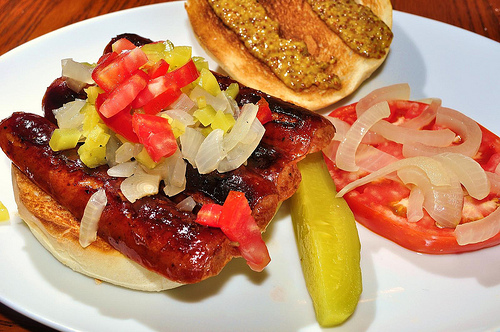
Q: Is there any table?
A: Yes, there is a table.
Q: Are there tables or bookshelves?
A: Yes, there is a table.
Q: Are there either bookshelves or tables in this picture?
A: Yes, there is a table.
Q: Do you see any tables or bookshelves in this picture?
A: Yes, there is a table.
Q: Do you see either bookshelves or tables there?
A: Yes, there is a table.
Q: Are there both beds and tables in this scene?
A: No, there is a table but no beds.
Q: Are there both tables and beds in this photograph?
A: No, there is a table but no beds.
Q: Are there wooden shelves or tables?
A: Yes, there is a wood table.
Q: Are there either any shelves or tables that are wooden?
A: Yes, the table is wooden.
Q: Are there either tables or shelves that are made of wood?
A: Yes, the table is made of wood.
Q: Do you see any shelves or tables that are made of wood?
A: Yes, the table is made of wood.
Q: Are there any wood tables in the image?
A: Yes, there is a wood table.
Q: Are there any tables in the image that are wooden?
A: Yes, there is a table that is wooden.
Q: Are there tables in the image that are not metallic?
A: Yes, there is a wooden table.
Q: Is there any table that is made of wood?
A: Yes, there is a table that is made of wood.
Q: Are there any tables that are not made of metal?
A: Yes, there is a table that is made of wood.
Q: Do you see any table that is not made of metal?
A: Yes, there is a table that is made of wood.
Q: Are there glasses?
A: No, there are no glasses.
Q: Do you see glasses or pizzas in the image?
A: No, there are no glasses or pizzas.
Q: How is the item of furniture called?
A: The piece of furniture is a table.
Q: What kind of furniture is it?
A: The piece of furniture is a table.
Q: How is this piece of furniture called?
A: This is a table.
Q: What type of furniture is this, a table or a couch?
A: This is a table.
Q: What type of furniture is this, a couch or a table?
A: This is a table.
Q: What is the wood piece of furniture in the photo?
A: The piece of furniture is a table.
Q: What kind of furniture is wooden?
A: The furniture is a table.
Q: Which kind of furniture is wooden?
A: The furniture is a table.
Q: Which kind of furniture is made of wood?
A: The furniture is a table.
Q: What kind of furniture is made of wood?
A: The furniture is a table.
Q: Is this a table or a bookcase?
A: This is a table.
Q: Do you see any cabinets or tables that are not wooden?
A: No, there is a table but it is wooden.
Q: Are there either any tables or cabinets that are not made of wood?
A: No, there is a table but it is made of wood.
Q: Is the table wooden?
A: Yes, the table is wooden.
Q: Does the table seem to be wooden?
A: Yes, the table is wooden.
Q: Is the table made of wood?
A: Yes, the table is made of wood.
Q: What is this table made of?
A: The table is made of wood.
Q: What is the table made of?
A: The table is made of wood.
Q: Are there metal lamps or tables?
A: No, there is a table but it is wooden.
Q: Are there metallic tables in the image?
A: No, there is a table but it is wooden.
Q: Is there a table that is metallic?
A: No, there is a table but it is wooden.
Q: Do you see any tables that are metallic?
A: No, there is a table but it is wooden.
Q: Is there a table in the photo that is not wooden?
A: No, there is a table but it is wooden.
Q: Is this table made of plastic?
A: No, the table is made of wood.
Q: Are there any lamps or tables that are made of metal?
A: No, there is a table but it is made of wood.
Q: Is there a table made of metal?
A: No, there is a table but it is made of wood.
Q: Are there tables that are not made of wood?
A: No, there is a table but it is made of wood.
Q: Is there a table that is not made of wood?
A: No, there is a table but it is made of wood.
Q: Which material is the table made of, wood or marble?
A: The table is made of wood.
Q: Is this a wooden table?
A: Yes, this is a wooden table.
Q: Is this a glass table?
A: No, this is a wooden table.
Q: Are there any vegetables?
A: Yes, there are vegetables.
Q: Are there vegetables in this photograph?
A: Yes, there are vegetables.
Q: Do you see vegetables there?
A: Yes, there are vegetables.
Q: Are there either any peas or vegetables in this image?
A: Yes, there are vegetables.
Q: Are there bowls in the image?
A: No, there are no bowls.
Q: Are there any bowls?
A: No, there are no bowls.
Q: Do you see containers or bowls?
A: No, there are no bowls or containers.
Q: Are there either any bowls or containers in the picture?
A: No, there are no bowls or containers.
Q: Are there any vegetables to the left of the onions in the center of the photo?
A: Yes, there are vegetables to the left of the onions.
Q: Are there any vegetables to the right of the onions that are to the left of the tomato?
A: No, the vegetables are to the left of the onions.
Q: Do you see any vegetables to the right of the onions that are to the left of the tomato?
A: No, the vegetables are to the left of the onions.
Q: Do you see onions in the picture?
A: Yes, there are onions.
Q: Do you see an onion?
A: Yes, there are onions.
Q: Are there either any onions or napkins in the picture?
A: Yes, there are onions.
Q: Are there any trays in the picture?
A: No, there are no trays.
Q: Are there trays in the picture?
A: No, there are no trays.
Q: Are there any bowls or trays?
A: No, there are no trays or bowls.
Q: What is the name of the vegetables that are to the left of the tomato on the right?
A: The vegetables are onions.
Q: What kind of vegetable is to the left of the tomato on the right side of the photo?
A: The vegetables are onions.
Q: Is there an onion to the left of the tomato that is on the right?
A: Yes, there are onions to the left of the tomato.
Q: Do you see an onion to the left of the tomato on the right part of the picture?
A: Yes, there are onions to the left of the tomato.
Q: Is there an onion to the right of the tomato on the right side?
A: No, the onions are to the left of the tomato.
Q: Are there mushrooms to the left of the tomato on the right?
A: No, there are onions to the left of the tomato.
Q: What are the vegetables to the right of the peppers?
A: The vegetables are onions.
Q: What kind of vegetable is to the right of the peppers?
A: The vegetables are onions.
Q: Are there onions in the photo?
A: Yes, there are onions.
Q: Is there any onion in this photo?
A: Yes, there are onions.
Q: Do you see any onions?
A: Yes, there are onions.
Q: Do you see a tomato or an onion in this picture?
A: Yes, there are onions.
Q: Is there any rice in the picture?
A: No, there is no rice.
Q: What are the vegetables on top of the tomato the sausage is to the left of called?
A: The vegetables are onions.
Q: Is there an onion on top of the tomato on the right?
A: Yes, there are onions on top of the tomato.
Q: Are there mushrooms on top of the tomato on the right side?
A: No, there are onions on top of the tomato.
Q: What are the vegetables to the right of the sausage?
A: The vegetables are onions.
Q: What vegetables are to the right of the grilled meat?
A: The vegetables are onions.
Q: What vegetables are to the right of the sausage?
A: The vegetables are onions.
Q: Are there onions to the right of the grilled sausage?
A: Yes, there are onions to the right of the sausage.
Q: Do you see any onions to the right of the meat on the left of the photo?
A: Yes, there are onions to the right of the sausage.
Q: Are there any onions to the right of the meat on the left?
A: Yes, there are onions to the right of the sausage.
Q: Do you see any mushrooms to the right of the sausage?
A: No, there are onions to the right of the sausage.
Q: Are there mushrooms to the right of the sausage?
A: No, there are onions to the right of the sausage.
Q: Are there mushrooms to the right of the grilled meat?
A: No, there are onions to the right of the sausage.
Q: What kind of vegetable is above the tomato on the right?
A: The vegetables are onions.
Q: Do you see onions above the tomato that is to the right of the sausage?
A: Yes, there are onions above the tomato.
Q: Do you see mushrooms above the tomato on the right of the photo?
A: No, there are onions above the tomato.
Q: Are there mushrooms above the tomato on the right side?
A: No, there are onions above the tomato.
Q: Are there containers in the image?
A: No, there are no containers.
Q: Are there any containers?
A: No, there are no containers.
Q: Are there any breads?
A: Yes, there is a bread.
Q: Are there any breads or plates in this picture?
A: Yes, there is a bread.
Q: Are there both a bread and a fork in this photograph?
A: No, there is a bread but no forks.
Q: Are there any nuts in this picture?
A: No, there are no nuts.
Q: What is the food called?
A: The food is a bread.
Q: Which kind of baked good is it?
A: The food is a bread.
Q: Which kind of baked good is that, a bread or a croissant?
A: This is a bread.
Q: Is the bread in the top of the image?
A: Yes, the bread is in the top of the image.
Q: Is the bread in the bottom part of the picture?
A: No, the bread is in the top of the image.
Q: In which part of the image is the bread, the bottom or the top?
A: The bread is in the top of the image.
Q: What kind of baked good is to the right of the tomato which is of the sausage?
A: The food is a bread.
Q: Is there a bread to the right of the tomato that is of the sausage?
A: Yes, there is a bread to the right of the tomato.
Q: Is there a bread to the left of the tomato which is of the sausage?
A: No, the bread is to the right of the tomato.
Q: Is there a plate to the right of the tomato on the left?
A: No, there is a bread to the right of the tomato.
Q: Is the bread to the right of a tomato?
A: Yes, the bread is to the right of a tomato.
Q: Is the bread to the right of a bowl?
A: No, the bread is to the right of a tomato.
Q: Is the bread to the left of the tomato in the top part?
A: No, the bread is to the right of the tomato.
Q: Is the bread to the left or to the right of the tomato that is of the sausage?
A: The bread is to the right of the tomato.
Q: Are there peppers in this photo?
A: Yes, there are peppers.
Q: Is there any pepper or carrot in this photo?
A: Yes, there are peppers.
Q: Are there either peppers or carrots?
A: Yes, there are peppers.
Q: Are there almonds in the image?
A: No, there are no almonds.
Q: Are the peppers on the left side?
A: Yes, the peppers are on the left of the image.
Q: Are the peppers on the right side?
A: No, the peppers are on the left of the image.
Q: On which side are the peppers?
A: The peppers are on the left of the image.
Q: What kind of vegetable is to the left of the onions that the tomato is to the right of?
A: The vegetables are peppers.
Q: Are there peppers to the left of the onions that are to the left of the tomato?
A: Yes, there are peppers to the left of the onions.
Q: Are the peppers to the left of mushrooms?
A: No, the peppers are to the left of the onions.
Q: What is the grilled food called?
A: The food is a sausage.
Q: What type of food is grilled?
A: The food is a sausage.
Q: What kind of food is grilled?
A: The food is a sausage.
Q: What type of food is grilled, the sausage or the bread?
A: The sausage is grilled.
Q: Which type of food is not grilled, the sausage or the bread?
A: The bread is not grilled.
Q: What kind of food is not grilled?
A: The food is a bread.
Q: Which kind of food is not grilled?
A: The food is a bread.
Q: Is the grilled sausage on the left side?
A: Yes, the sausage is on the left of the image.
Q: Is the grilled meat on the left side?
A: Yes, the sausage is on the left of the image.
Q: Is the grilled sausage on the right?
A: No, the sausage is on the left of the image.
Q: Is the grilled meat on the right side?
A: No, the sausage is on the left of the image.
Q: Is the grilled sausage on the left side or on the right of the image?
A: The sausage is on the left of the image.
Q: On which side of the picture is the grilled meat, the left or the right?
A: The sausage is on the left of the image.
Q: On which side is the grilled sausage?
A: The sausage is on the left of the image.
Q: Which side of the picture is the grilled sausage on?
A: The sausage is on the left of the image.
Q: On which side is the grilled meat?
A: The sausage is on the left of the image.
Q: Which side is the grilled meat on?
A: The sausage is on the left of the image.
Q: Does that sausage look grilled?
A: Yes, the sausage is grilled.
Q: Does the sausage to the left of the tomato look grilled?
A: Yes, the sausage is grilled.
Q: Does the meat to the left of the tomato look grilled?
A: Yes, the sausage is grilled.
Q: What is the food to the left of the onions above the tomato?
A: The food is a sausage.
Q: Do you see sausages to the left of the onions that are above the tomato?
A: Yes, there is a sausage to the left of the onions.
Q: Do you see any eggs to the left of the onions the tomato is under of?
A: No, there is a sausage to the left of the onions.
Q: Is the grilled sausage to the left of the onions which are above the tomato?
A: Yes, the sausage is to the left of the onions.